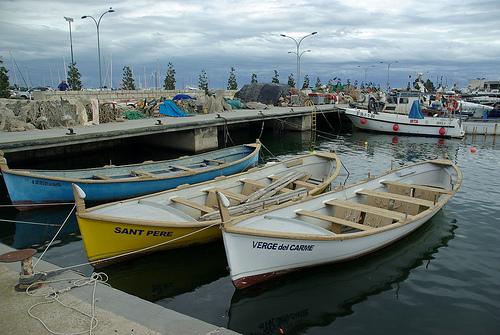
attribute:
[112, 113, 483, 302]
water — rippled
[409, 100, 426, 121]
shirt — blue 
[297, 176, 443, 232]
bench — wooden 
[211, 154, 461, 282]
boat — white 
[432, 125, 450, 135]
saver —  orange life , hanging up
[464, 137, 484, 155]
buoy — floating, orange 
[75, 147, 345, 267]
boat — yellow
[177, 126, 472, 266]
boat — white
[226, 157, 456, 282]
boat — white 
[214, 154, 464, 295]
boat — white 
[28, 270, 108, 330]
rope — white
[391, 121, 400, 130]
buoy — red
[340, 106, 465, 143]
boat — small, white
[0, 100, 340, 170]
dock — long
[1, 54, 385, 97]
trees — green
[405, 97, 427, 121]
tarp — blue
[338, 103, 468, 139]
boat — white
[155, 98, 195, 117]
tarp — blue